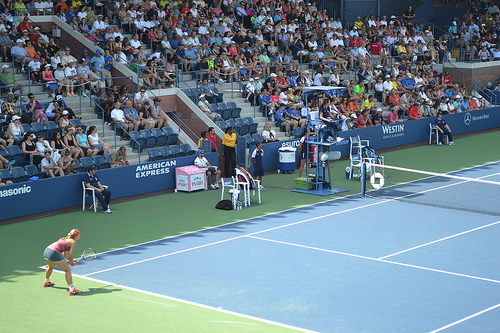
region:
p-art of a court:
[408, 221, 423, 243]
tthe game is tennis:
[3, 6, 495, 328]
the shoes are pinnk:
[62, 281, 84, 298]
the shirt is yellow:
[219, 132, 240, 149]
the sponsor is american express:
[132, 165, 179, 182]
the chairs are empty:
[141, 124, 188, 154]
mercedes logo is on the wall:
[459, 111, 488, 125]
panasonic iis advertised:
[2, 182, 32, 198]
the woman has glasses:
[22, 130, 39, 150]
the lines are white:
[137, 246, 164, 266]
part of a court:
[305, 278, 333, 330]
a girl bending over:
[36, 215, 107, 302]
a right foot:
[48, 285, 91, 298]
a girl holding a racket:
[30, 214, 99, 273]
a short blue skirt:
[36, 245, 73, 275]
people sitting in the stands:
[0, 69, 183, 185]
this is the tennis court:
[233, 219, 490, 314]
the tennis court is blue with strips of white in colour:
[282, 229, 476, 318]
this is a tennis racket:
[72, 247, 95, 263]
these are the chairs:
[135, 130, 176, 142]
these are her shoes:
[69, 287, 81, 293]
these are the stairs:
[84, 105, 95, 121]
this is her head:
[69, 227, 79, 239]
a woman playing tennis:
[37, 214, 102, 313]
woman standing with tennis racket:
[42, 229, 97, 296]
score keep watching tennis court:
[77, 165, 112, 213]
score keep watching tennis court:
[427, 114, 455, 147]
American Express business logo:
[131, 158, 178, 180]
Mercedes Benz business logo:
[460, 109, 492, 126]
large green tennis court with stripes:
[44, 160, 499, 330]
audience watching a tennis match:
[2, 0, 499, 185]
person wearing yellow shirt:
[220, 126, 239, 179]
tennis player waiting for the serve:
[35, 224, 98, 301]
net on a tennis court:
[356, 156, 498, 223]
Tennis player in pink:
[37, 225, 99, 300]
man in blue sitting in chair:
[78, 163, 113, 213]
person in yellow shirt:
[219, 122, 240, 177]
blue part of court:
[53, 126, 496, 328]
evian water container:
[172, 159, 208, 191]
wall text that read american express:
[130, 158, 176, 179]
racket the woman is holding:
[71, 247, 102, 264]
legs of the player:
[43, 259, 75, 284]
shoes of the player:
[43, 276, 83, 296]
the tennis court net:
[356, 154, 499, 229]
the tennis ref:
[302, 82, 349, 199]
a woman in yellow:
[224, 126, 237, 175]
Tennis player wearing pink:
[35, 228, 89, 298]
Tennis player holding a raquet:
[21, 224, 105, 300]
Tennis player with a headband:
[41, 224, 97, 298]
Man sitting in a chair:
[78, 165, 118, 216]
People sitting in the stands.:
[1, 4, 496, 165]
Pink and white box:
[172, 163, 207, 195]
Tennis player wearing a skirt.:
[24, 226, 101, 295]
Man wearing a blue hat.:
[80, 163, 115, 213]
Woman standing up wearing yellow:
[220, 123, 238, 175]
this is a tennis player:
[19, 215, 105, 303]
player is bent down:
[40, 215, 100, 296]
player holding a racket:
[61, 240, 104, 276]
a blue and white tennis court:
[59, 149, 498, 329]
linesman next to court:
[299, 84, 350, 144]